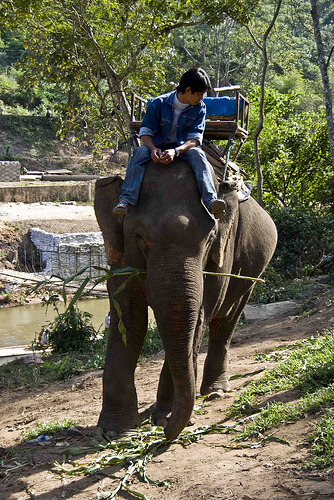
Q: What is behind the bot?
A: A chair.